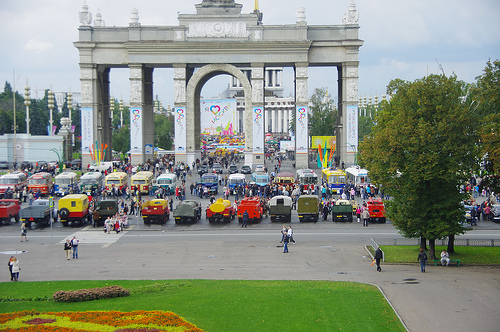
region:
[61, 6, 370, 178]
a monument in the city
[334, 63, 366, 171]
the column of monument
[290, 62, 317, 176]
the column of monument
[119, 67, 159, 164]
the column of monument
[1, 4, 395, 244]
cars in front a monument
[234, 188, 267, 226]
the car is red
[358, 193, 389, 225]
the car is red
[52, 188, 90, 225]
the car is red and yellow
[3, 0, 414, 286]
people in front a monument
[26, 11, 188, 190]
buses in front a monument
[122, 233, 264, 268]
The street is made of asphalt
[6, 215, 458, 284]
A lot of people on the ground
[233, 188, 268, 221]
The truck is the color red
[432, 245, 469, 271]
A person sitting on the bench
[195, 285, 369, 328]
The grass is short and green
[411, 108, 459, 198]
The leaves on the tree are green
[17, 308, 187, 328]
The grass is colored orange and yellow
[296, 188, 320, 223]
The color of the truck is green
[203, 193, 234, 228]
The color of the truck is red and yellow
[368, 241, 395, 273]
The person is walking in the street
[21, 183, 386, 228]
the trucks are parked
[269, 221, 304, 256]
people walking at the park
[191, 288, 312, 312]
many green grass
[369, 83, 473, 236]
a leafy tree to the right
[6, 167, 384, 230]
many vehicles of different colors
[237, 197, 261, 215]
this vehicle is red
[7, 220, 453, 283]
several people on the scene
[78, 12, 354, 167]
the momnument of arc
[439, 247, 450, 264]
this person is sitting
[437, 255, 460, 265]
this is a green bench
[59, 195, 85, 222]
a yellow and red vehicle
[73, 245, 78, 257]
this person is wearing a blue jeans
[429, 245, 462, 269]
person sitting on a bench under a giant tree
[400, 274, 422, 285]
two oil spots near the entrance to the parking lot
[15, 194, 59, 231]
older model flat bed truck painted gray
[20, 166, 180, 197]
six buses parked side by side in a parking lot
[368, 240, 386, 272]
man carrying an orange bag walking towards entrance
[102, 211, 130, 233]
group of people walking together through several rows of parked vehicles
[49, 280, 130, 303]
row of pretty pink flowers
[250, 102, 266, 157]
banner with blue, green, yellow, pink and purple hearts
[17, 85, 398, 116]
row of many stadium lights surrounding the venue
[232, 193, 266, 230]
person standing behind a bright red truck